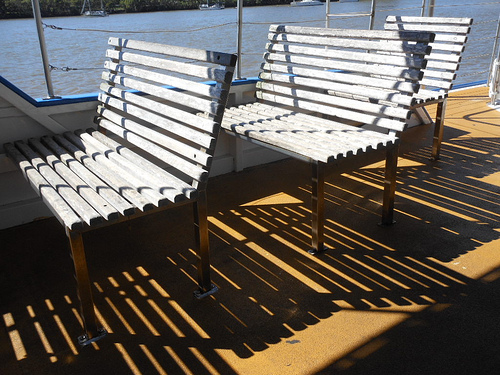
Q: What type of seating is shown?
A: Benches.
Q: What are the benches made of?
A: Wood.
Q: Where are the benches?
A: On a boat.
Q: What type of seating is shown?
A: Benches.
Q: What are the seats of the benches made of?
A: Wood.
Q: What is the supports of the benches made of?
A: Metal.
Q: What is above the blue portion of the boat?
A: Wire barrier.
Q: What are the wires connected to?
A: Metal poles.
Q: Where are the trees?
A: Far shore.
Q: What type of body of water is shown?
A: River.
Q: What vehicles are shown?
A: Boats.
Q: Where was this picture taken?
A: On a boat.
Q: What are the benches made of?
A: Wood.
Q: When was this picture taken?
A: In the daytime.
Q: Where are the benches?
A: Bolted to the deck.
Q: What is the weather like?
A: Sunny.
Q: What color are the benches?
A: Gray.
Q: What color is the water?
A: Blue.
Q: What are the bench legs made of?
A: Metal.